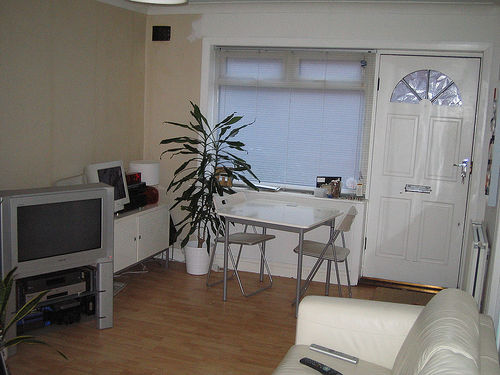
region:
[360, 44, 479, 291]
a white front door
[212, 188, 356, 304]
folding table and chairs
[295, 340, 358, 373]
two remotes sitting on the couch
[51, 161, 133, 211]
a white computer monitor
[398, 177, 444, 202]
a place for the mail to come in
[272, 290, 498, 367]
a white leather couch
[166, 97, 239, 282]
a tall green plant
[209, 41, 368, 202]
closed window blinds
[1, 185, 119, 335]
tv on a tv stand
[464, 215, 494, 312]
a vent against the wall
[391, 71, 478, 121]
Window at the top of a door.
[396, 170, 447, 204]
Mail slot on a door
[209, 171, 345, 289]
White card table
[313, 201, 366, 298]
White and silver folding chair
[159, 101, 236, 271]
Leafy house plant in a white pot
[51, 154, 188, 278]
Computer monitor on a white shelf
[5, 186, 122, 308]
Silver TV on a TV stand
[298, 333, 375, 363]
Silver remote control on a white couch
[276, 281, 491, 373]
White couch with two remote controls on it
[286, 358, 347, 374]
Black remote control on a white couch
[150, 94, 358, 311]
A tree sitting next to a table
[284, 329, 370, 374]
Two remote controls on a white couch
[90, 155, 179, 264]
A computer sits on the desk in the corner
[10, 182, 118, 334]
An older model silver television and video player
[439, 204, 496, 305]
A folding table leaning against the wall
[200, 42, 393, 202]
Mini blinds cover the window with no curtains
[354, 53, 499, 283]
A white door with a metallic knob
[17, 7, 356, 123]
The walls have not been completely painted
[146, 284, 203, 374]
A brown hard wood floor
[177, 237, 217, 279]
A white flower pot sitting on the brown wood floor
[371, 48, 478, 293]
white paneled front door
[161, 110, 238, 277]
standing long leaf artificial tree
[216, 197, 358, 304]
white table with two chairs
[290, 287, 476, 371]
corner of white sofa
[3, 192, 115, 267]
silver small screened tv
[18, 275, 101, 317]
black vcr and silver dvd player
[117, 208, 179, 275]
white cabinet stand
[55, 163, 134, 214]
white box computer monitor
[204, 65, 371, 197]
large window blinds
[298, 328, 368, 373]
black and silver remotes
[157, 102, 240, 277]
A large plant in a white planter.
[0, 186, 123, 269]
A television.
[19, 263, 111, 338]
Electronic devices attached to the television.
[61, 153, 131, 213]
A computer monitor is behind the television.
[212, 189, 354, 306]
A small table and chairs.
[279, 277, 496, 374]
A white sofa.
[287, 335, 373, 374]
Two remote controls.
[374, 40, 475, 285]
A door.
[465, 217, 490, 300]
A radiator.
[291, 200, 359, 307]
A folding chair.